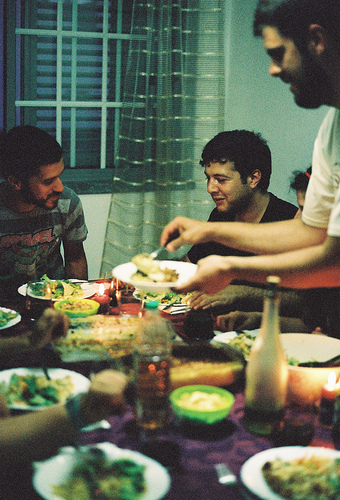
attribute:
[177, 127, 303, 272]
man — young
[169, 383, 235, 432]
bowl — green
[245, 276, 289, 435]
bottle — half-full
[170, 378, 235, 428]
bowl — green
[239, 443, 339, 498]
plate — white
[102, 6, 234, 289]
curtains — sheer, slippery, stripes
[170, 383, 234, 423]
bowl — green, yellowish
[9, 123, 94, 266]
man — black, grey, striped